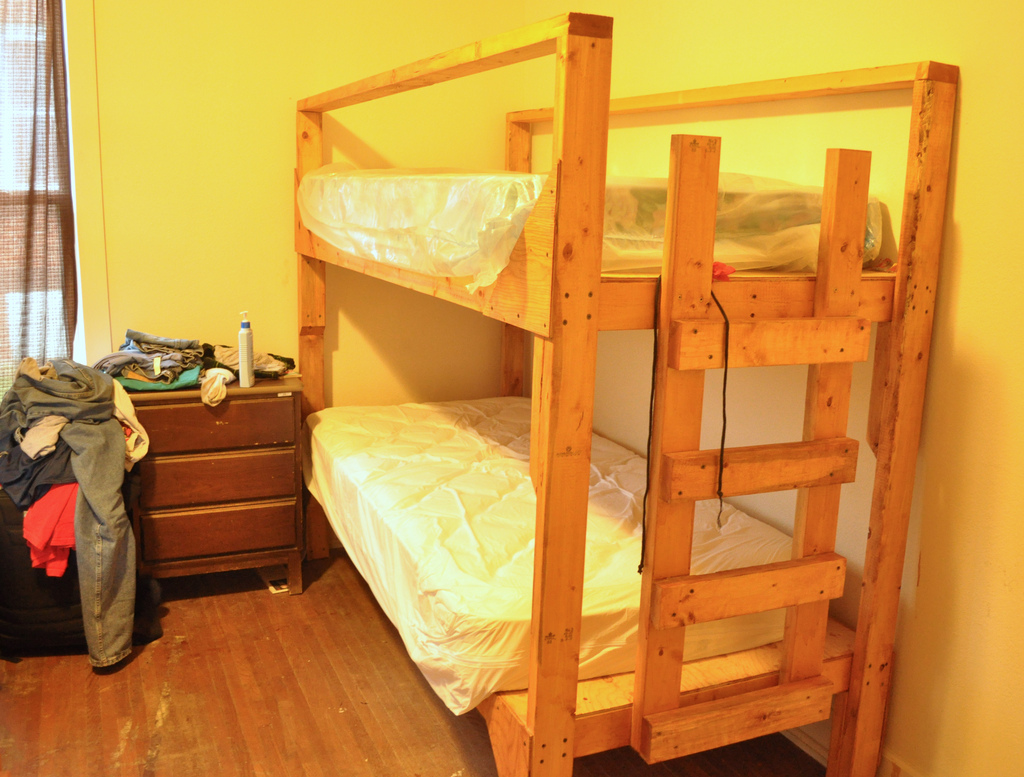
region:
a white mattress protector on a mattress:
[326, 392, 821, 678]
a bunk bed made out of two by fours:
[275, 10, 964, 773]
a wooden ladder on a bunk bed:
[624, 133, 868, 762]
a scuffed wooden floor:
[114, 639, 250, 775]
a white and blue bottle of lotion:
[234, 304, 264, 403]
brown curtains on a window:
[1, 0, 88, 365]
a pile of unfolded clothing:
[10, 350, 150, 651]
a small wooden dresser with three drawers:
[102, 373, 306, 614]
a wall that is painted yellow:
[74, 2, 565, 402]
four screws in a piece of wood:
[550, 284, 609, 336]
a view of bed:
[312, 139, 559, 326]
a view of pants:
[28, 439, 175, 662]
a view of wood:
[264, 612, 362, 756]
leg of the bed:
[492, 364, 584, 605]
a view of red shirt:
[32, 490, 106, 611]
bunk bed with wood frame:
[293, 13, 958, 775]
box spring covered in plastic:
[304, 390, 801, 697]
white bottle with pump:
[234, 307, 253, 388]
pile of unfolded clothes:
[0, 359, 146, 667]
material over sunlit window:
[1, 2, 78, 373]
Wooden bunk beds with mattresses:
[291, 13, 958, 773]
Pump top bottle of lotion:
[234, 307, 258, 390]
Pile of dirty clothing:
[13, 358, 143, 660]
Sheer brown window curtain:
[6, 3, 74, 358]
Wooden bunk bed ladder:
[637, 135, 865, 765]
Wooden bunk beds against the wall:
[255, 14, 951, 770]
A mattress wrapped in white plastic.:
[293, 373, 840, 686]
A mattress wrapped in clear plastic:
[298, 172, 915, 291]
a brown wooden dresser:
[105, 374, 331, 606]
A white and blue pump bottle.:
[226, 304, 274, 397]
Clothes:
[9, 313, 152, 661]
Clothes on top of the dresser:
[72, 317, 304, 410]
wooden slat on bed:
[637, 679, 846, 766]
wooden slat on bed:
[645, 556, 851, 618]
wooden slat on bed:
[660, 429, 885, 506]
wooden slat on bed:
[659, 306, 876, 373]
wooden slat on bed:
[637, 124, 726, 758]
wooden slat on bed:
[493, 102, 538, 178]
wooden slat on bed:
[294, 105, 337, 413]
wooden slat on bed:
[594, 272, 904, 333]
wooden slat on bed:
[511, 57, 960, 133]